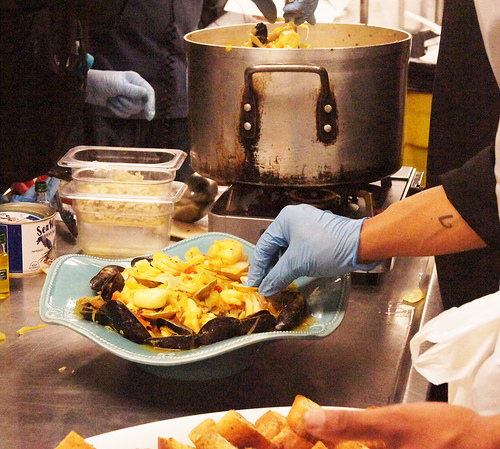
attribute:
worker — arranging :
[254, 157, 484, 290]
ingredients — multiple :
[1, 196, 57, 296]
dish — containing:
[79, 175, 167, 254]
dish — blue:
[72, 222, 314, 353]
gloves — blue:
[234, 189, 373, 300]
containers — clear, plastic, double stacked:
[46, 134, 199, 251]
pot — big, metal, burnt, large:
[178, 18, 430, 188]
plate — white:
[52, 399, 463, 446]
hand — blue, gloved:
[257, 0, 319, 26]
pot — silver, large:
[182, 19, 412, 180]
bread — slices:
[154, 396, 384, 445]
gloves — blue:
[243, 192, 383, 305]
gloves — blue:
[91, 57, 159, 119]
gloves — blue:
[239, 0, 332, 23]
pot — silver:
[182, 4, 423, 195]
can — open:
[9, 200, 58, 282]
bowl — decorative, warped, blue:
[39, 232, 349, 378]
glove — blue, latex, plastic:
[245, 203, 383, 293]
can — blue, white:
[0, 202, 59, 276]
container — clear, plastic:
[60, 176, 188, 256]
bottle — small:
[0, 239, 11, 300]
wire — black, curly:
[148, 20, 179, 150]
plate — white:
[85, 406, 368, 445]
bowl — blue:
[30, 234, 375, 416]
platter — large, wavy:
[40, 250, 323, 383]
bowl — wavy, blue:
[29, 238, 355, 357]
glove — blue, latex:
[225, 200, 396, 305]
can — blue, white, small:
[16, 210, 80, 276]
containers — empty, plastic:
[57, 139, 170, 223]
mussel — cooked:
[86, 300, 165, 343]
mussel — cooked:
[227, 305, 317, 348]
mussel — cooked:
[269, 288, 313, 333]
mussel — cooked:
[89, 265, 124, 289]